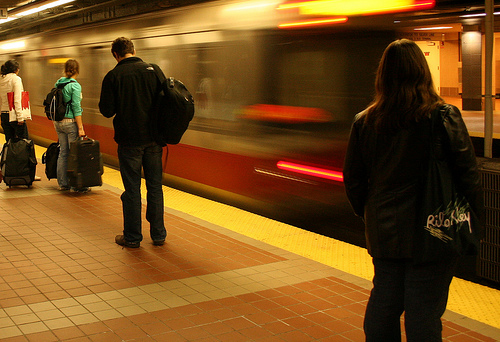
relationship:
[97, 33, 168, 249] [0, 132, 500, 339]
boy on sidewalk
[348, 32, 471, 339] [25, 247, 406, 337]
leg person are at platform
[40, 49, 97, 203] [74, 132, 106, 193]
girl carrying suitcase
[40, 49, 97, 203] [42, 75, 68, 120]
girl carrying suitcase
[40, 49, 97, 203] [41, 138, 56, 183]
girl carrying suitcase